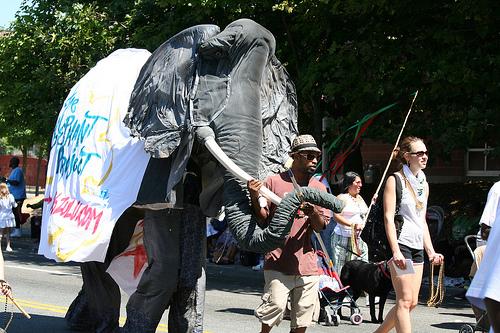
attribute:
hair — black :
[333, 163, 364, 200]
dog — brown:
[340, 260, 390, 321]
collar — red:
[373, 261, 390, 285]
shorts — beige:
[253, 270, 327, 332]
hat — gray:
[288, 134, 323, 155]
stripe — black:
[290, 143, 317, 149]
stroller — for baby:
[303, 227, 363, 324]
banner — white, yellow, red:
[23, 48, 208, 275]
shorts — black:
[380, 236, 427, 267]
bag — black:
[361, 173, 403, 262]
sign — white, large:
[50, 45, 159, 269]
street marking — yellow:
[3, 272, 201, 332]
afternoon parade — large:
[2, 0, 499, 332]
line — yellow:
[9, 287, 64, 314]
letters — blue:
[58, 97, 116, 229]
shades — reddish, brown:
[410, 140, 429, 160]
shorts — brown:
[263, 263, 319, 325]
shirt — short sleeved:
[266, 151, 352, 247]